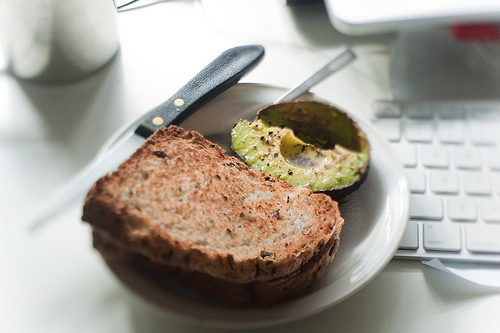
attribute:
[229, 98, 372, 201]
avocado — half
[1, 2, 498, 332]
desk — white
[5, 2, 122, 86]
computer mouse — white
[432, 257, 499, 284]
paper — white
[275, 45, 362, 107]
handle — silver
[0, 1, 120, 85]
mug — white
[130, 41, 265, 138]
handle — black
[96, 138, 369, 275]
toast — slice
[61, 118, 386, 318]
bread — toasted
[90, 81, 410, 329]
plate — white, breakfast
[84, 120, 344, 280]
bread — slices, seasoned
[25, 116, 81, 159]
desk — white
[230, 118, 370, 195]
avocado — half eaten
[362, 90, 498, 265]
keyboard — white